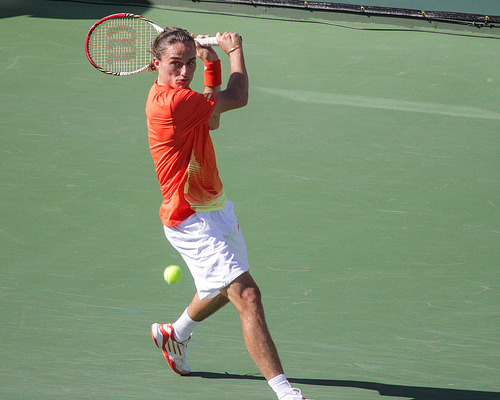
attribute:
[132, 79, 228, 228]
shirt — orange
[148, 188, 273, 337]
shorts — white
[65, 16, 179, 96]
racket — for tennis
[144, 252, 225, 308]
ball — for tennis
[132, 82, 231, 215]
shirt — orange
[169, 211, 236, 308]
shorts — white